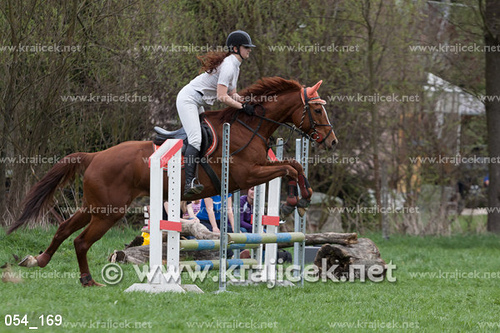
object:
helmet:
[224, 30, 256, 56]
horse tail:
[3, 151, 92, 237]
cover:
[303, 79, 328, 100]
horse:
[3, 76, 342, 289]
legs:
[241, 160, 299, 207]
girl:
[174, 29, 259, 199]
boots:
[176, 143, 212, 196]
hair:
[193, 51, 232, 76]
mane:
[239, 74, 305, 96]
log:
[310, 235, 386, 283]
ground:
[0, 215, 499, 332]